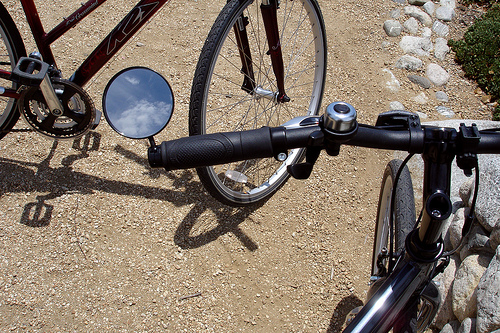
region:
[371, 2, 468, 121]
rocks in the dirt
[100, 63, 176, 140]
the bike has a mirror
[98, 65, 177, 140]
the mirror is round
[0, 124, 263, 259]
a shadow of the bike on the ground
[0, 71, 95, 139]
the bike has a chain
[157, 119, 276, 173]
the bike has a black handlebar grip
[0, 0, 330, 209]
the bike is red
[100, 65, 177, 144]
a reflection of the sky in the mirror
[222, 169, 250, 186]
the bike tire has a white reflector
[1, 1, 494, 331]
the bikes are on dirt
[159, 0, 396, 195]
the wheel on a bike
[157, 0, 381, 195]
the front wheel on a bjke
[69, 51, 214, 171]
the mirror on a bike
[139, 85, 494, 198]
the handle bars on a bike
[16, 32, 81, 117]
the paddle on a bike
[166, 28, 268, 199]
the tire on a bike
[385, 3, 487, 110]
rocks near a bike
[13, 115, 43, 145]
the chain on a bike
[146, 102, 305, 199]
a rubber grip on a bike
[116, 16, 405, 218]
a bike sitting on the dirt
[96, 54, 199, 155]
mirror on bicycle handlebars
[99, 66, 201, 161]
mirror reflecting image of clouds in sky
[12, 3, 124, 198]
kick stand down on bike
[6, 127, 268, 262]
shadow from bike on ground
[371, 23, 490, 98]
rocks buried in the dirt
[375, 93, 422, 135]
reflector on the front of bike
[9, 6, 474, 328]
sandy, rocky ground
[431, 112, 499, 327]
stones stacked up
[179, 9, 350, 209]
front bike wheel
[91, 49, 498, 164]
handlebars on mountain bike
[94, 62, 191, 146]
clouds reflected in a bicycle mirror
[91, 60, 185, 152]
a mirror on a bike's handle bars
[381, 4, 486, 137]
gray stones lying along a brown path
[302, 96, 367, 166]
ta bell attached to a bike's handlebars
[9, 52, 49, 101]
the pedal on a bike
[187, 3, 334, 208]
the spokes on a bike wheel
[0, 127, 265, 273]
shadow of a bicycle on the grouns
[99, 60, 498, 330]
a bike leaning on a pile of rocks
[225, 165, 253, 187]
the reflector the spokes of bike wheel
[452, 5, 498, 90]
a bush growing on the side of a dirt road